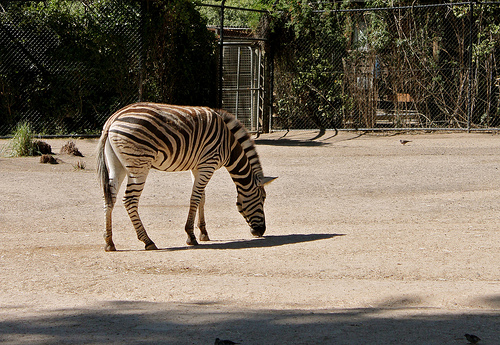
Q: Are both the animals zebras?
A: No, they are birds and zebras.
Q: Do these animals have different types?
A: Yes, they are birds and zebras.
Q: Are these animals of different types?
A: Yes, they are birds and zebras.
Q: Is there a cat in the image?
A: No, there are no cats.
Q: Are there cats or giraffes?
A: No, there are no cats or giraffes.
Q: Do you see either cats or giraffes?
A: No, there are no cats or giraffes.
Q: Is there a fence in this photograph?
A: Yes, there is a fence.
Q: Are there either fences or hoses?
A: Yes, there is a fence.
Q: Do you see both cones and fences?
A: No, there is a fence but no cones.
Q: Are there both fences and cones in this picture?
A: No, there is a fence but no cones.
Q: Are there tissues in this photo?
A: No, there are no tissues.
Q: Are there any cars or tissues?
A: No, there are no tissues or cars.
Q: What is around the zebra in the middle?
A: The fence is around the zebra.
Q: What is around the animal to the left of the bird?
A: The fence is around the zebra.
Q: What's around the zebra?
A: The fence is around the zebra.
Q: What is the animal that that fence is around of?
A: The animal is a zebra.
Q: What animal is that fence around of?
A: The fence is around the zebra.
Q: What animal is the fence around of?
A: The fence is around the zebra.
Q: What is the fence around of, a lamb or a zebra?
A: The fence is around a zebra.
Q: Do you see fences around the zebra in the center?
A: Yes, there is a fence around the zebra.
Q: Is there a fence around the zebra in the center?
A: Yes, there is a fence around the zebra.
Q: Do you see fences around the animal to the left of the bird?
A: Yes, there is a fence around the zebra.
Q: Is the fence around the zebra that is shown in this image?
A: Yes, the fence is around the zebra.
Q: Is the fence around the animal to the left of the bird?
A: Yes, the fence is around the zebra.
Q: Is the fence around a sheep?
A: No, the fence is around the zebra.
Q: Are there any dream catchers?
A: No, there are no dream catchers.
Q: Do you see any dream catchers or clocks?
A: No, there are no dream catchers or clocks.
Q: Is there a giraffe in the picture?
A: No, there are no giraffes.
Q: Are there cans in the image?
A: No, there are no cans.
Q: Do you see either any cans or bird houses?
A: No, there are no cans or bird houses.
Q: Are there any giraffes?
A: No, there are no giraffes.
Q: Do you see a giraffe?
A: No, there are no giraffes.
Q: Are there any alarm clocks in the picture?
A: No, there are no alarm clocks.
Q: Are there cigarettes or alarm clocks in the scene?
A: No, there are no alarm clocks or cigarettes.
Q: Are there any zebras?
A: Yes, there is a zebra.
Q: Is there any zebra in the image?
A: Yes, there is a zebra.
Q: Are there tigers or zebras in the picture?
A: Yes, there is a zebra.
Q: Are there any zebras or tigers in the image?
A: Yes, there is a zebra.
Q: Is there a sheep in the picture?
A: No, there is no sheep.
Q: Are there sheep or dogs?
A: No, there are no sheep or dogs.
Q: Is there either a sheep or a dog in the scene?
A: No, there are no sheep or dogs.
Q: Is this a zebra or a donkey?
A: This is a zebra.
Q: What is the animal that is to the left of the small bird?
A: The animal is a zebra.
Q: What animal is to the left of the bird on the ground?
A: The animal is a zebra.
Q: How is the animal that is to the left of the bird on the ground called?
A: The animal is a zebra.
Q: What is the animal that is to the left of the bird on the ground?
A: The animal is a zebra.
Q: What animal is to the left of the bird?
A: The animal is a zebra.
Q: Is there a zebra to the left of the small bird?
A: Yes, there is a zebra to the left of the bird.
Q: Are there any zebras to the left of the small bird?
A: Yes, there is a zebra to the left of the bird.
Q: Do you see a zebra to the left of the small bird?
A: Yes, there is a zebra to the left of the bird.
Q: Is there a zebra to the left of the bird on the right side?
A: Yes, there is a zebra to the left of the bird.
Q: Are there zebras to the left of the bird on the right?
A: Yes, there is a zebra to the left of the bird.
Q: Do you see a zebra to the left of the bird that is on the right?
A: Yes, there is a zebra to the left of the bird.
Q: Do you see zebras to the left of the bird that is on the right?
A: Yes, there is a zebra to the left of the bird.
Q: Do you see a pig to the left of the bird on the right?
A: No, there is a zebra to the left of the bird.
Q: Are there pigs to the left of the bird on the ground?
A: No, there is a zebra to the left of the bird.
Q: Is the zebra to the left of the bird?
A: Yes, the zebra is to the left of the bird.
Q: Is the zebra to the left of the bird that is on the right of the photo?
A: Yes, the zebra is to the left of the bird.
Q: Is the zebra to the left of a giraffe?
A: No, the zebra is to the left of the bird.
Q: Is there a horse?
A: No, there are no horses.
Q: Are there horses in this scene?
A: No, there are no horses.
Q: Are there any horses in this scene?
A: No, there are no horses.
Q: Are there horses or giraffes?
A: No, there are no horses or giraffes.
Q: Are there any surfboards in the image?
A: No, there are no surfboards.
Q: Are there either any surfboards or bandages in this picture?
A: No, there are no surfboards or bandages.